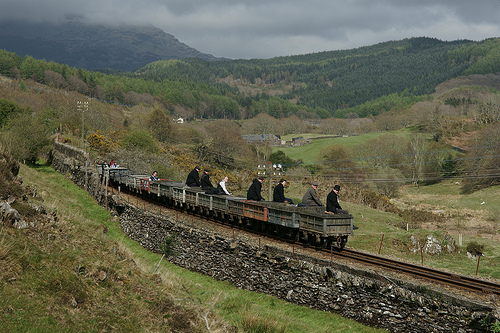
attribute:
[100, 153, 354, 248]
train — small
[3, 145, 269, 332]
hillside — rocky, grassy, green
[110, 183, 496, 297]
tracks — iron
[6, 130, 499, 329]
field — green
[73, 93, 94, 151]
lights — wooden, tall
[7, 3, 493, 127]
mountains — green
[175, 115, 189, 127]
house — white, small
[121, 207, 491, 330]
wall — brick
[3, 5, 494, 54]
clouds — coming in, dark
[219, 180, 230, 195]
sleeve — white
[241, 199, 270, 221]
cart — orange